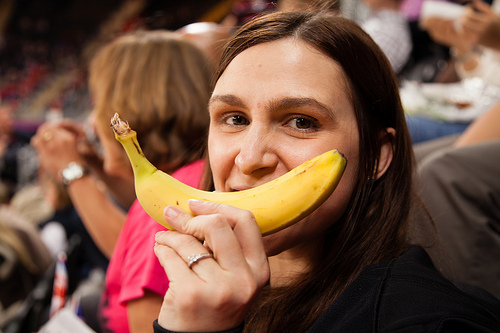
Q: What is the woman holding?
A: A banana.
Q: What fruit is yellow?
A: The banana.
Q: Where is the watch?
A: On the person's arm.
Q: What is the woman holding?
A: Banana.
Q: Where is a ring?
A: Around a woman's finger.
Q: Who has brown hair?
A: Woman holding banana.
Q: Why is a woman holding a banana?
A: To eat it.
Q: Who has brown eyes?
A: The brunette woman.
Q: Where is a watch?
A: Around a person's arm.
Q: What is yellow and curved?
A: The banana.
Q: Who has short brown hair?
A: Woman in pink.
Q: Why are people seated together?
A: To watch a game.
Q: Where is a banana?
A: In lady's left hand.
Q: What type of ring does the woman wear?
A: An engagement ring.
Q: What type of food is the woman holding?
A: A banana.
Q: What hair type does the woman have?
A: Brunette.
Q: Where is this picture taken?
A: An audience.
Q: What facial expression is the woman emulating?
A: A smile.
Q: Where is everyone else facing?
A: Towards the action.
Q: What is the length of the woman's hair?
A: Shoulder length.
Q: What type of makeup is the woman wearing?
A: No makeup.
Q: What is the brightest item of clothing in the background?
A: A pink shirt.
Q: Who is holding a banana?
A: The woman.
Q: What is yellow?
A: The banana.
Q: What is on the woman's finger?
A: A ring.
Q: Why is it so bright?
A: Lights are on.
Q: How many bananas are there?
A: One.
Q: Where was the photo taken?
A: An arena.